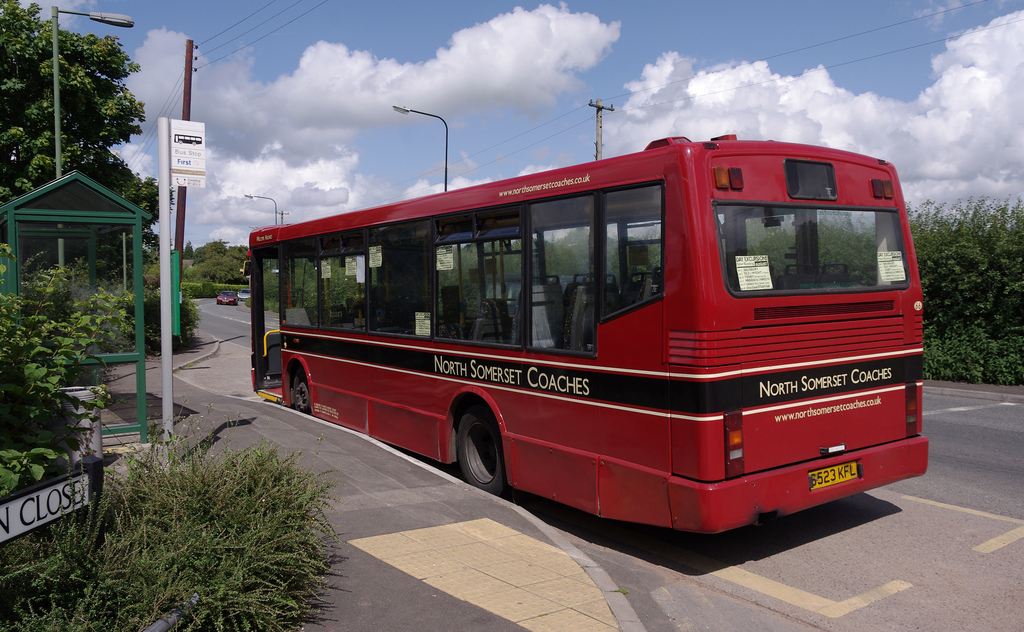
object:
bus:
[246, 133, 930, 535]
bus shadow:
[510, 489, 905, 574]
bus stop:
[0, 169, 150, 446]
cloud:
[121, 1, 620, 147]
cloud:
[117, 141, 360, 225]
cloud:
[603, 12, 1020, 213]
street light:
[392, 104, 458, 192]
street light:
[63, 34, 146, 167]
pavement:
[101, 294, 1023, 629]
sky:
[2, 1, 1021, 249]